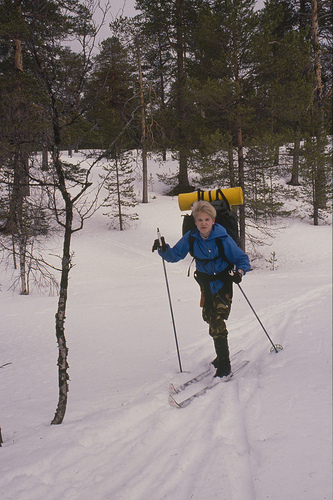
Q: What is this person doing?
A: Skiing.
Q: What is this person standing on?
A: Skis.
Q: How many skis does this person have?
A: Two.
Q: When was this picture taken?
A: Daytime.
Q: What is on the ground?
A: Snow.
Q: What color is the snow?
A: White.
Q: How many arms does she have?
A: Two.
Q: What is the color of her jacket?
A: Blue.